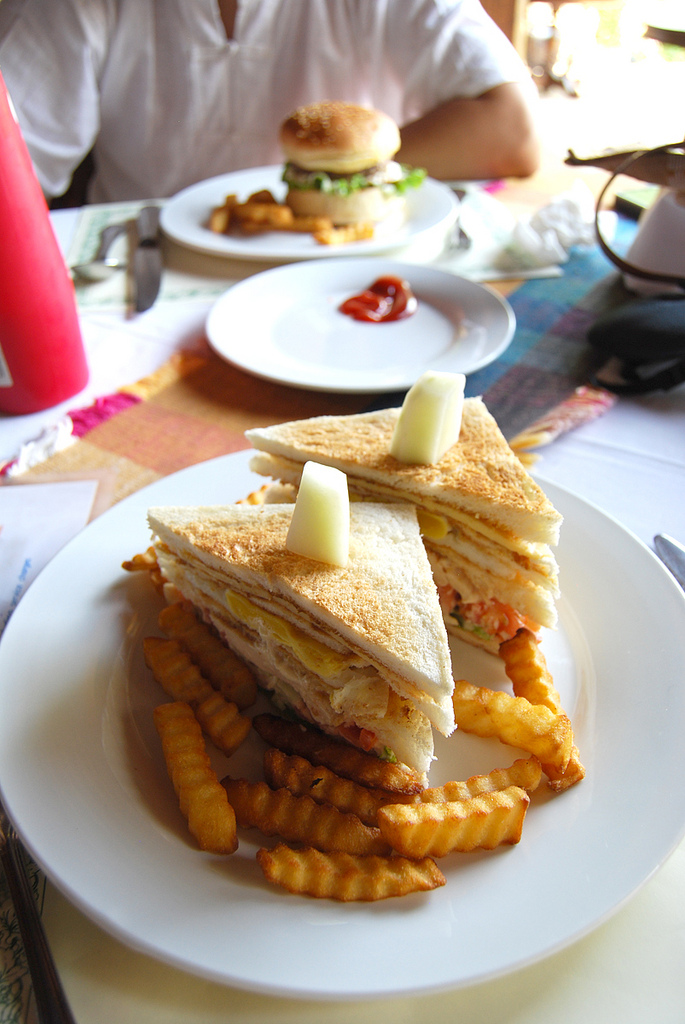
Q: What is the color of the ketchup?
A: Red.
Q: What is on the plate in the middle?
A: Ketchup.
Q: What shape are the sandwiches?
A: Triangle.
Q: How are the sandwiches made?
A: Toasted.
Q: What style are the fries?
A: Crinkle.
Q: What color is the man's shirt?
A: White.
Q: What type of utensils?
A: Spoon fork and knife.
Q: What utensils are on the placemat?
A: Spoon and knife.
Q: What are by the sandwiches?
A: Fries.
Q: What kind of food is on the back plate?
A: Burger.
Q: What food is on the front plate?
A: Sandwich and fries.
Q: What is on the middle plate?
A: Ketchup.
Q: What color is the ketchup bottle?
A: Red.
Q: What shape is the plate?
A: Round.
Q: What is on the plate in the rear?
A: Hamburger.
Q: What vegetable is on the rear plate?
A: Lettuce.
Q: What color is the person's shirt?
A: White.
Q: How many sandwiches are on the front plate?
A: Two.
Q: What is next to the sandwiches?
A: French fries.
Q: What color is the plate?
A: White.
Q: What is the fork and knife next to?
A: Plate.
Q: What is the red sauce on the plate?
A: Ketchup.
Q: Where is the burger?
A: On the plate in the background.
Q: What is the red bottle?
A: A ketchup bottle.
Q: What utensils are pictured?
A: A spoon and a knife.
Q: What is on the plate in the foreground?
A: A sandwich and fries.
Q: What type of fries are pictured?
A: Crinkle cut fries.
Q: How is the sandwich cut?
A: In half diagonally.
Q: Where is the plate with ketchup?
A: In the center of the table.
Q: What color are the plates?
A: White.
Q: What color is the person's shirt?
A: White.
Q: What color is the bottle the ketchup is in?
A: Red.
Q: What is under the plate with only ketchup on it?
A: A plaid placemat.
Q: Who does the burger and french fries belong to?
A: The person in the white shirt.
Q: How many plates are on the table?
A: Three.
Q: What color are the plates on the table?
A: White.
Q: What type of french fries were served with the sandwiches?
A: Crinkle-cut fries.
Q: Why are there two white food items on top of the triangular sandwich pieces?
A: It is a garnish.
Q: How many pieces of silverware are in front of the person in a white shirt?
A: Three.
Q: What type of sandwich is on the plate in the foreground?
A: A Triple Decker.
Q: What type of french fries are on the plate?
A: Crinkle cut.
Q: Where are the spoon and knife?
A: On the right side of the plate.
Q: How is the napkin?
A: Crumpled.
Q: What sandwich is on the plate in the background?
A: A burger.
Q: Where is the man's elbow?
A: On the table.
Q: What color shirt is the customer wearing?
A: White.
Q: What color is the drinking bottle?
A: Red.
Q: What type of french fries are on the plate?
A: Crinkle-cut.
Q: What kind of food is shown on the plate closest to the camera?
A: Sandwich and fries.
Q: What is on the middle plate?
A: Ketchup.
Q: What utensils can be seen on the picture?
A: Knife and spoon.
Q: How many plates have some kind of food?
A: 3.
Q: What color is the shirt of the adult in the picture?
A: White.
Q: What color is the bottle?
A: Red.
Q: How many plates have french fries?
A: 2.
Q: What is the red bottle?
A: A ketchup bottle.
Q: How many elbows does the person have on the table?
A: 1.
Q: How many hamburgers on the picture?
A: One.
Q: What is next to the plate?
A: Knife and spoon.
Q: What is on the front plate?
A: Sandwich and fries.